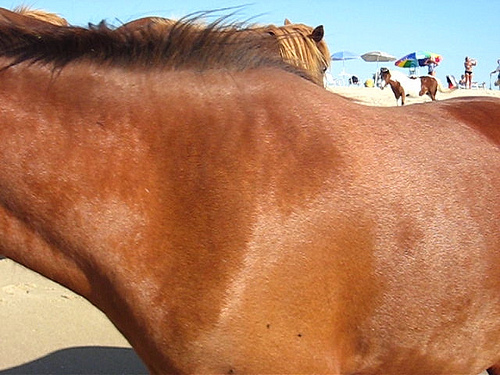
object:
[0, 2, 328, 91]
mane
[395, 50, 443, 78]
umbrella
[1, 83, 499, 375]
beach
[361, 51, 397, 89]
umbrella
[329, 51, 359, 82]
umbrella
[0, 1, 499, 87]
sky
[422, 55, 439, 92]
people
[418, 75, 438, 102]
horse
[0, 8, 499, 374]
flank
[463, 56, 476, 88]
woman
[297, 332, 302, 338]
black mark